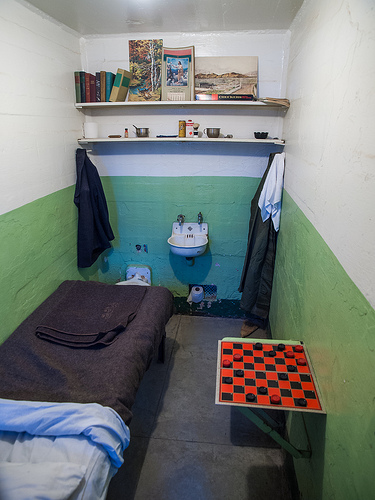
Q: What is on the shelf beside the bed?
A: Checker board.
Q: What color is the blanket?
A: Gray.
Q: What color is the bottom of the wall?
A: Green.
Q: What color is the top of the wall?
A: White.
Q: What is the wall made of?
A: Concrete.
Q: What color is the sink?
A: White.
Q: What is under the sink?
A: Toilet paper.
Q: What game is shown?
A: Checkers.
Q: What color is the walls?
A: Green and white.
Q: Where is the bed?
A: On left.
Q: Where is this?
A: Jail.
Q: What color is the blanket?
A: Brown.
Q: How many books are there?
A: Eight.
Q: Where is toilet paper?
A: Wall next to floor.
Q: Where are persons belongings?
A: Shelves.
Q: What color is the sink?
A: White.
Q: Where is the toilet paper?
A: On the shelf.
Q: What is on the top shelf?
A: Books.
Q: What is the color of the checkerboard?
A: Black and red.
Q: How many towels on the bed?
A: One.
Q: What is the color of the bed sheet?
A: Blue.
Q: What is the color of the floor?
A: Gray.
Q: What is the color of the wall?
A: Green.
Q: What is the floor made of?
A: Cement.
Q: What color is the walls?
A: White and green.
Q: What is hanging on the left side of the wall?
A: A jacket.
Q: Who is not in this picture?
A: The inmate.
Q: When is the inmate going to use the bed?
A: During lockdown for sleeping.